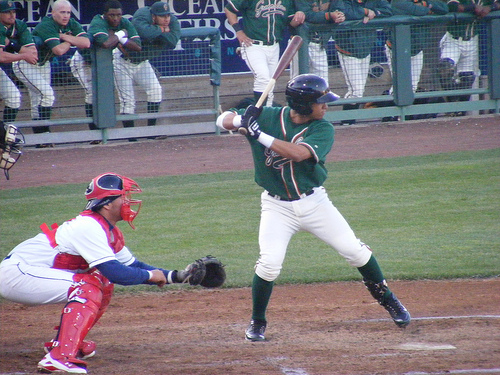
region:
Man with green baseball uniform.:
[207, 30, 422, 350]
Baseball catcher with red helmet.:
[0, 164, 246, 371]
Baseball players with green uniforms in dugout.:
[6, 8, 223, 136]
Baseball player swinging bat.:
[209, 27, 415, 372]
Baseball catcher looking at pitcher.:
[6, 152, 236, 358]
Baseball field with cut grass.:
[14, 9, 484, 349]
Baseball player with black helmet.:
[7, 35, 447, 368]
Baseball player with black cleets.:
[209, 53, 442, 349]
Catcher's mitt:
[146, 235, 238, 311]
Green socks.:
[239, 246, 415, 347]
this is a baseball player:
[220, 50, 375, 350]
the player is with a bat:
[230, 30, 306, 122]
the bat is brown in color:
[265, 30, 302, 76]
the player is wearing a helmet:
[287, 80, 334, 101]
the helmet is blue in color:
[287, 78, 335, 103]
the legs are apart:
[244, 236, 394, 334]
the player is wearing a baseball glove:
[163, 256, 231, 293]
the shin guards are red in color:
[63, 287, 110, 353]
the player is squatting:
[1, 164, 161, 373]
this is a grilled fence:
[364, 24, 489, 91]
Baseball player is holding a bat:
[186, 5, 453, 342]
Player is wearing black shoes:
[233, 234, 453, 359]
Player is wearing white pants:
[217, 186, 424, 365]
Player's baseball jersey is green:
[196, 86, 396, 224]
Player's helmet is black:
[251, 56, 388, 156]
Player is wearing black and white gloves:
[224, 101, 292, 155]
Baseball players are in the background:
[2, 2, 489, 99]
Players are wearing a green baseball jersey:
[3, 5, 498, 77]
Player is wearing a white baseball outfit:
[13, 161, 232, 374]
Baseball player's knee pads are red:
[55, 261, 125, 346]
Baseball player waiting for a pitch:
[216, 31, 417, 346]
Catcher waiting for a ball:
[0, 171, 238, 374]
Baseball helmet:
[282, 71, 341, 125]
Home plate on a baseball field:
[387, 333, 468, 359]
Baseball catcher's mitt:
[175, 250, 231, 291]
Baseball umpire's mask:
[0, 114, 29, 183]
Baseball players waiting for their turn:
[83, 0, 191, 140]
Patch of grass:
[385, 164, 486, 251]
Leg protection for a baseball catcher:
[36, 266, 116, 374]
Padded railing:
[203, 23, 225, 90]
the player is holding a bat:
[221, 67, 349, 189]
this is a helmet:
[288, 72, 333, 108]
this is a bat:
[278, 24, 303, 66]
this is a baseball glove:
[183, 254, 225, 289]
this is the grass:
[169, 176, 231, 250]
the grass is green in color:
[401, 175, 436, 205]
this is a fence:
[140, 37, 182, 102]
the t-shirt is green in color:
[262, 169, 281, 185]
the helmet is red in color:
[93, 185, 99, 192]